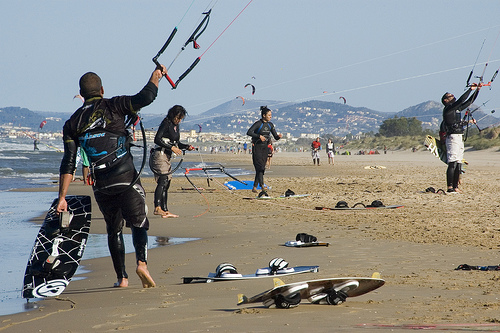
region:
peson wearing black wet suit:
[69, 97, 154, 226]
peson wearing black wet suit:
[151, 123, 180, 180]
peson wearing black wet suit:
[247, 125, 265, 167]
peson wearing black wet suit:
[434, 103, 463, 180]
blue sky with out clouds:
[25, 15, 87, 49]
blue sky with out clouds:
[6, 39, 40, 77]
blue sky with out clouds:
[259, 23, 324, 55]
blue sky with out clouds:
[353, 23, 413, 52]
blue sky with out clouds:
[334, 46, 388, 78]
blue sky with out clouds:
[419, 12, 489, 49]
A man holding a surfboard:
[16, 187, 94, 302]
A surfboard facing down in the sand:
[232, 270, 397, 310]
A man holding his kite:
[146, 3, 254, 95]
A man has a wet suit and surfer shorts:
[53, 60, 165, 295]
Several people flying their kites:
[13, 74, 497, 301]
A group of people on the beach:
[194, 140, 255, 159]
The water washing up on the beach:
[2, 134, 34, 322]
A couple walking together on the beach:
[305, 133, 346, 171]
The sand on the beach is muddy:
[217, 192, 472, 314]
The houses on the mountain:
[228, 93, 363, 138]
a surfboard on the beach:
[228, 266, 388, 313]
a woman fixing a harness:
[147, 103, 194, 219]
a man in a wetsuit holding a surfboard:
[16, 62, 167, 300]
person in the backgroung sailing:
[23, 117, 50, 150]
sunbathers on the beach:
[339, 147, 381, 157]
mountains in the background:
[205, 94, 497, 137]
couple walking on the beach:
[308, 134, 338, 167]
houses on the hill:
[281, 105, 383, 140]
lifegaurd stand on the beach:
[187, 127, 199, 144]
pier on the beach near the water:
[0, 118, 32, 139]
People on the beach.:
[5, 58, 493, 328]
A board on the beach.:
[166, 238, 332, 279]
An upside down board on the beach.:
[227, 265, 387, 316]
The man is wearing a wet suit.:
[46, 58, 164, 294]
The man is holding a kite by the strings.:
[137, 6, 257, 83]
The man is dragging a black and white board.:
[15, 187, 88, 313]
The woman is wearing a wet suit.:
[146, 91, 206, 216]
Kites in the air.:
[222, 75, 357, 105]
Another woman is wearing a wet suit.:
[241, 98, 282, 198]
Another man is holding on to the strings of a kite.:
[427, 23, 499, 209]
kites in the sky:
[230, 78, 353, 108]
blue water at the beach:
[0, 138, 212, 323]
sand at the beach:
[139, 145, 498, 330]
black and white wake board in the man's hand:
[19, 190, 94, 306]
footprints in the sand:
[293, 167, 482, 243]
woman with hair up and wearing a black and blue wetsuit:
[246, 105, 283, 192]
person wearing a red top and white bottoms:
[308, 133, 326, 165]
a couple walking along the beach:
[307, 135, 339, 164]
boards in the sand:
[185, 189, 406, 309]